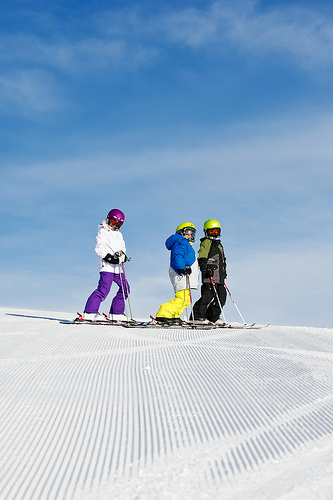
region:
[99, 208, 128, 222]
A purple sketting helmet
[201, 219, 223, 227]
A green sketting helmet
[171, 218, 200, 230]
A green sketting helmet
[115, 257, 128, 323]
A long slim sketting rod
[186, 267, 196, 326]
A long slim sketting rod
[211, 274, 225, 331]
A long slim sketting rod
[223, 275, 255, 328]
A long slim sketting rod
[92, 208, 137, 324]
A beautiful sketing suit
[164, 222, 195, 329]
A beautiful sketing suit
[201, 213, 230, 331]
A beautiful sketing suit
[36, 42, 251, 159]
this is the sky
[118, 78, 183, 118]
the sky is blue in color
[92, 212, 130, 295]
this is a man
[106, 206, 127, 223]
this is a helmet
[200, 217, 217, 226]
the helmet is yellow in color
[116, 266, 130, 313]
this is a stick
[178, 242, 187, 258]
this is a jacket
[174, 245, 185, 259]
the jacket is blue in color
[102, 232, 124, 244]
the jacket is white in color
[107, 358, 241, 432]
this is the snow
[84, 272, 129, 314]
a pair of purple snow pants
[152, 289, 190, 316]
a pair of yellow snow pants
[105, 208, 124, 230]
a purple ski helmet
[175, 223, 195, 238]
a yellow ski helmet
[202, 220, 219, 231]
a yellow ski helmet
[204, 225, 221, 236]
protective eye wear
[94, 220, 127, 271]
a white winter coat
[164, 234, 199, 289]
a blue and white winter coat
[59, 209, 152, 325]
a girl on snow skis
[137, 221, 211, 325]
a girl on snow skis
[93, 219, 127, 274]
A hooded white parka.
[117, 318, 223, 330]
A pair of skis.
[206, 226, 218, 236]
A sun visor on a helmet.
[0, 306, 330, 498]
Crisp, white packed snow for skiing.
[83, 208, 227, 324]
Three people on a ski slope.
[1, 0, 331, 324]
Blue sky with little cloud coverage.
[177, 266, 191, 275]
A black gloved hand.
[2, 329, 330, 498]
Vertical and criss cross patterns in the snow.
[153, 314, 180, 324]
A woman wearing black ski boots.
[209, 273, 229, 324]
A man holding a ski pole in his right hand.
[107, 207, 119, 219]
helmet is a bright purple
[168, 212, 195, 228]
ski helmet is bright yellow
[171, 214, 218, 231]
two yellow helmets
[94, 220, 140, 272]
ski jacket is white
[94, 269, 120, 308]
ski pants are purple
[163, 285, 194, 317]
ski pants are bright yellow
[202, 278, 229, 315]
ski pants are black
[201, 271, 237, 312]
skis are red, black and white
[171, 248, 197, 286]
ski jacket is blue and white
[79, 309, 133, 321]
ski boots are white